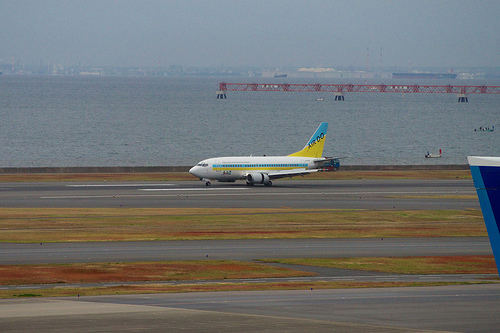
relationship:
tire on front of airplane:
[195, 175, 212, 201] [118, 120, 368, 185]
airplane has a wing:
[187, 121, 350, 186] [251, 160, 329, 192]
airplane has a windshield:
[187, 121, 350, 186] [189, 149, 219, 174]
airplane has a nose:
[145, 101, 379, 211] [166, 142, 216, 192]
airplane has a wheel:
[187, 121, 350, 186] [260, 167, 282, 196]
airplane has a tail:
[187, 121, 350, 186] [275, 117, 363, 166]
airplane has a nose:
[187, 121, 350, 186] [187, 153, 199, 192]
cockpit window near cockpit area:
[196, 162, 206, 168] [180, 149, 239, 197]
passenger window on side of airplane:
[213, 156, 324, 188] [187, 121, 350, 186]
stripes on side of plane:
[202, 146, 332, 188] [143, 99, 410, 219]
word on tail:
[300, 127, 349, 160] [282, 103, 359, 170]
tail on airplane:
[282, 103, 359, 170] [187, 121, 350, 186]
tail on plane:
[290, 117, 346, 174] [166, 120, 362, 208]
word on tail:
[307, 132, 325, 148] [290, 117, 346, 174]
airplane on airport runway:
[187, 121, 350, 186] [2, 180, 478, 208]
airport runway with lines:
[2, 180, 478, 208] [66, 180, 244, 191]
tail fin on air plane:
[287, 121, 328, 156] [186, 121, 348, 183]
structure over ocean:
[213, 82, 498, 100] [7, 83, 489, 164]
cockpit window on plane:
[196, 162, 210, 168] [189, 120, 344, 187]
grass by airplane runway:
[1, 206, 489, 243] [7, 166, 497, 330]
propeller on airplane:
[238, 170, 256, 183] [187, 121, 350, 186]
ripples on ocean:
[24, 134, 93, 157] [7, 83, 489, 164]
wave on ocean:
[127, 113, 158, 136] [7, 83, 489, 164]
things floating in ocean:
[423, 123, 497, 158] [7, 83, 489, 164]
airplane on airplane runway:
[187, 121, 350, 186] [0, 180, 497, 330]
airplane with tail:
[187, 121, 350, 186] [292, 122, 345, 172]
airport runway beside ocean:
[2, 180, 478, 208] [7, 83, 489, 164]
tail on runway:
[469, 154, 499, 284] [2, 275, 498, 331]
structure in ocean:
[213, 82, 498, 100] [7, 83, 489, 164]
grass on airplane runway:
[1, 205, 486, 244] [0, 180, 497, 330]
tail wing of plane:
[306, 120, 348, 171] [189, 120, 344, 187]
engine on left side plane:
[244, 170, 270, 186] [189, 120, 344, 187]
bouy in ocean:
[422, 149, 442, 157] [7, 83, 489, 164]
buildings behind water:
[119, 60, 180, 90] [113, 65, 254, 144]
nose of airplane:
[187, 163, 199, 178] [187, 121, 350, 186]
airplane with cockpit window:
[187, 121, 350, 186] [196, 162, 206, 168]